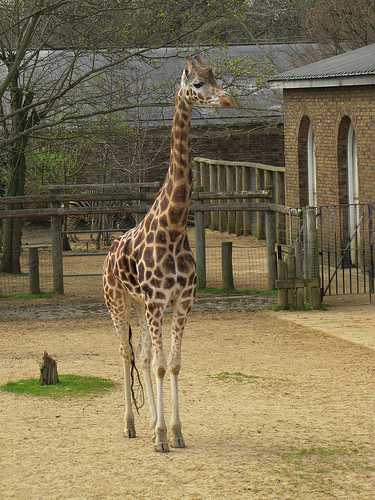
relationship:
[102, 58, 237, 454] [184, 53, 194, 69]
giraffe with horn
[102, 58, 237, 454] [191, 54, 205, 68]
giraffe with horn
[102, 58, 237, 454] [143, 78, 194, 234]
giraffe with neck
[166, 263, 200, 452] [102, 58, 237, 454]
leg on giraffe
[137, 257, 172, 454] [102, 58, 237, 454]
leg on giraffe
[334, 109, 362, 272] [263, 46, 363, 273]
arch on building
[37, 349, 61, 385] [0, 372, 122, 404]
wood in grass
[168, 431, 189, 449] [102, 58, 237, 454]
hoof on giraffe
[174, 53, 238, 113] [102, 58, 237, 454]
head of giraffe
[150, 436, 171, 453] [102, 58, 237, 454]
hoof of giraffe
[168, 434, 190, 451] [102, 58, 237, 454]
hoof of giraffe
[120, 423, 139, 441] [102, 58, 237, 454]
hoof of giraffe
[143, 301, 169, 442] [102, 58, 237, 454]
leg of giraffe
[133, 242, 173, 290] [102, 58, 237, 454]
spots on giraffe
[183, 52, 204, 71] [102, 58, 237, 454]
horns on giraffe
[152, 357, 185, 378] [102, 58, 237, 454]
knees of giraffe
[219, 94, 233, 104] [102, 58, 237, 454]
nose of giraffe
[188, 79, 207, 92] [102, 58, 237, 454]
eye of giraffe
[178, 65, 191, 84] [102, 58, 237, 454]
ear of giraffe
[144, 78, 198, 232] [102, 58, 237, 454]
neck of giraffe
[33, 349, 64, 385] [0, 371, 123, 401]
wood on grass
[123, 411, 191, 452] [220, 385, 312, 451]
feet are on ground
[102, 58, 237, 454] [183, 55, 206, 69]
giraffe has two small horns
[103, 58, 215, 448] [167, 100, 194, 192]
giraffe has a long neck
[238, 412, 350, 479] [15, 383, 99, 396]
ground has a few grasses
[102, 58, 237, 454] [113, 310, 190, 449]
giraffe has a thin legs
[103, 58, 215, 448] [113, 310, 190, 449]
giraffe has legs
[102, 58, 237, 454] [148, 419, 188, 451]
giraffe has hooves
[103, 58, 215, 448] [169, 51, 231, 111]
giraffe has a head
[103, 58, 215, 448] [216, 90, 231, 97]
giraffe has a nose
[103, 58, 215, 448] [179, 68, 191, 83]
giraffe has an ear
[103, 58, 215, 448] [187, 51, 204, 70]
giraffe have horns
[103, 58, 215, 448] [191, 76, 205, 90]
giraffe has an eye